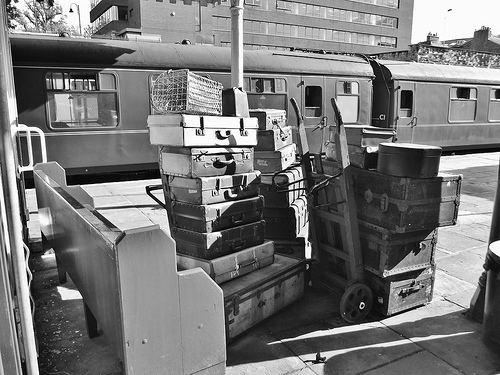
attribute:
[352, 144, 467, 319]
chests — three 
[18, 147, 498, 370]
sidewalk — grey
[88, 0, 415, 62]
building — large 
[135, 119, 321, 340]
luggage — top 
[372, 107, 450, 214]
box — circular 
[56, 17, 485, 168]
train — dark